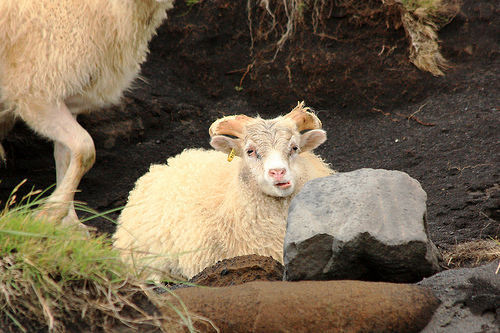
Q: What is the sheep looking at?
A: The camera.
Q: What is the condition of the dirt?
A: Moist.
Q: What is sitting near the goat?
A: A large rock.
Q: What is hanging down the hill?
A: Roots.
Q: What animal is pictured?
A: Goats.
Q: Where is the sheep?
A: On ground.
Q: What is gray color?
A: Rock.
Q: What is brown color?
A: Rock.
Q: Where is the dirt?
A: On ground.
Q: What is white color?
A: Sheep.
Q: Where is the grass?
A: Under goat.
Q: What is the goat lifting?
A: Left.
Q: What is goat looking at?
A: Camera.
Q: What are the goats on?
A: Rocks.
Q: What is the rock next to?
A: A goat.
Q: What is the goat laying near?
A: A rock.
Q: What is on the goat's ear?
A: A tag.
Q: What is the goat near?
A: Green grass.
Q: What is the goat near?
A: Long grass.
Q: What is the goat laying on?
A: The ground.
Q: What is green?
A: The grass.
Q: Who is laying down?
A: The animal.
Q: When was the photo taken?
A: Day time.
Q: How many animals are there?
A: Two.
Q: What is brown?
A: The dirt.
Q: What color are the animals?
A: Tan.